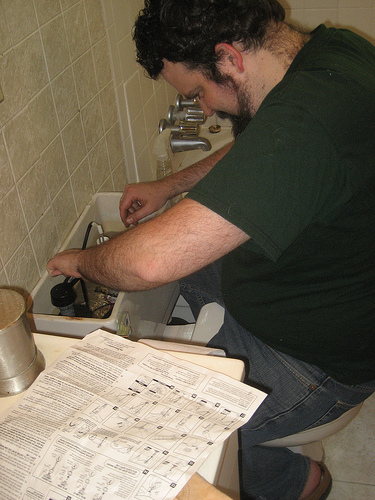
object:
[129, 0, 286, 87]
hair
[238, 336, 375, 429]
seat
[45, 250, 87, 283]
hand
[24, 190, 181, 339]
bowl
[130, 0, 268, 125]
head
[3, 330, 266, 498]
instruction manual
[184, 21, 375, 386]
shirt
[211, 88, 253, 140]
beard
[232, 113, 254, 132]
chin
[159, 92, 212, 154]
attached faucets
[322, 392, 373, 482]
tile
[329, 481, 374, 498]
tile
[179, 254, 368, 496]
blue jeans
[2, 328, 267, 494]
paper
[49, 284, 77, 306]
knob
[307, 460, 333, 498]
sandals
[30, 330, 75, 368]
sink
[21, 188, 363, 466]
toilet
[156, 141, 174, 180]
bottle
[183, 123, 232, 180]
tub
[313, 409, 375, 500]
floor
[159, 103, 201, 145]
silver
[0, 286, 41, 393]
bowl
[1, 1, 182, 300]
tiled wall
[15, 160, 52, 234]
tile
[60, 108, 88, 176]
tile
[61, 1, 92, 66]
tile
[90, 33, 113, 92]
tile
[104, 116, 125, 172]
tile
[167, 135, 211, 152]
faucet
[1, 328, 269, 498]
diagram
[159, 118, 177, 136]
taps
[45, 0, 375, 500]
guy